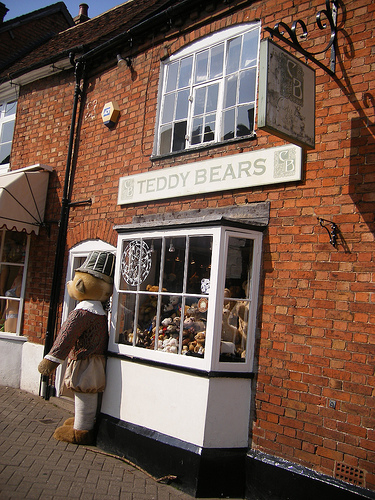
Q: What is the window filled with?
A: Stuffed animals.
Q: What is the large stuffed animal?
A: Teddy Bear.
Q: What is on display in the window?
A: Teddy Bears.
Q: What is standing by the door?
A: A large teddy bear.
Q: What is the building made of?
A: Brick.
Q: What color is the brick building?
A: Red.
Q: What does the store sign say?
A: Teddy Bears.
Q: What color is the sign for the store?
A: White.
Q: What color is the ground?
A: Brown.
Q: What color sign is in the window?
A: White.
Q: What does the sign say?
A: TEDDY BEARS.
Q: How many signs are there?
A: 2.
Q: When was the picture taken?
A: Daytime.